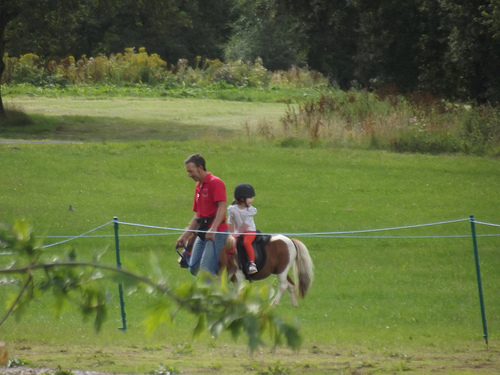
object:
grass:
[0, 137, 499, 375]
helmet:
[234, 183, 256, 211]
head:
[233, 183, 255, 208]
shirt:
[192, 172, 229, 233]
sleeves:
[212, 179, 227, 202]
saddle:
[236, 230, 272, 280]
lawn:
[279, 145, 499, 235]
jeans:
[189, 230, 229, 284]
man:
[174, 154, 228, 314]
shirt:
[227, 204, 258, 234]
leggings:
[227, 230, 256, 262]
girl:
[226, 183, 258, 274]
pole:
[468, 214, 488, 351]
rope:
[0, 217, 500, 255]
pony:
[177, 215, 315, 320]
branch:
[0, 216, 305, 358]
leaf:
[218, 322, 303, 359]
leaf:
[266, 285, 275, 303]